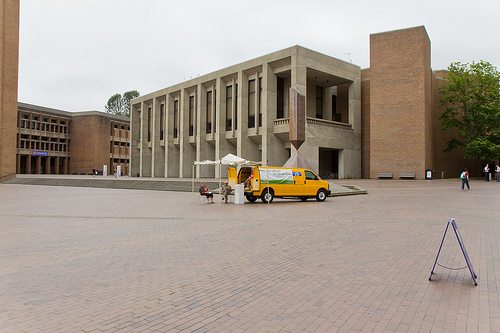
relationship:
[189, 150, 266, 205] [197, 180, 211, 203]
canopy covering men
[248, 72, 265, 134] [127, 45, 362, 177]
long window on building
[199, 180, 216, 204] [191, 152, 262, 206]
men under canopy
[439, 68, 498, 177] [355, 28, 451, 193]
tree by building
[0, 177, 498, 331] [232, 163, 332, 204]
brick walkway around van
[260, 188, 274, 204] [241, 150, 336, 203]
tire on van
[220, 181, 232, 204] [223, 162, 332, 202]
man behind van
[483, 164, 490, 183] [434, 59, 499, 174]
man standing near tree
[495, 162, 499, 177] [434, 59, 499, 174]
people standing near tree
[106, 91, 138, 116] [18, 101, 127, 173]
tree behind building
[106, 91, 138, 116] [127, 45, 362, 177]
tree behind building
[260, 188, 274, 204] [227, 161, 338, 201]
tire on van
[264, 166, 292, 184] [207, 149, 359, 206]
sign on van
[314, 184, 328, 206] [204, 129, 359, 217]
tire on van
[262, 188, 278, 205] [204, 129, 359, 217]
tire on van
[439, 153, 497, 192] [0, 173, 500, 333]
people walking walking on brick walkway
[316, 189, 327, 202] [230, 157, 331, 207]
tire on van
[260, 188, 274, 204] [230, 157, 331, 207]
tire on van